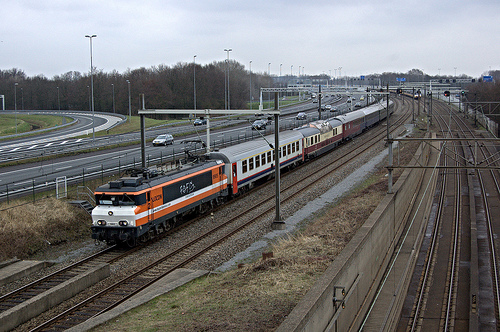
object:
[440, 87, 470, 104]
street lights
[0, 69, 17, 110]
trees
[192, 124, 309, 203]
carriage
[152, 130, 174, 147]
cars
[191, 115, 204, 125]
cars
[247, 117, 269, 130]
cars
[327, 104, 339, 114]
cars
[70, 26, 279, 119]
light poles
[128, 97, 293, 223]
rails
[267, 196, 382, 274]
soil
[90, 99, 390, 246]
train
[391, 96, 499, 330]
rail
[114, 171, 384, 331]
grass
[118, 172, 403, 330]
gravel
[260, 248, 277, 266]
tree stump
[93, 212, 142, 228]
headlights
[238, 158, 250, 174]
window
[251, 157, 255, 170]
window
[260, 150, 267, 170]
window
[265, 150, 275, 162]
window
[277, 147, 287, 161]
window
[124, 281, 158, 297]
rail line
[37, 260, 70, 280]
rail line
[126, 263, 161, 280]
rail line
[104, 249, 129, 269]
rail line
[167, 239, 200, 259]
rail line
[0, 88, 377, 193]
highway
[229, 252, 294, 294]
grass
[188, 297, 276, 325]
dirt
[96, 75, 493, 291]
train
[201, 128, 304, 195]
train car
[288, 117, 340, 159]
train car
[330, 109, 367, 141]
train car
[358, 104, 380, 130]
train car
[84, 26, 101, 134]
lighting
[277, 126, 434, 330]
barrier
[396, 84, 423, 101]
train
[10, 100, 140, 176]
highway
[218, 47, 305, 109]
street lights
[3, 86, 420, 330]
rail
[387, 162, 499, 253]
tracks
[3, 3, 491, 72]
grey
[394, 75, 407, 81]
billboard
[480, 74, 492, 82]
billboard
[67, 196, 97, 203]
stairs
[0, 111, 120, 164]
road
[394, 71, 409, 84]
signs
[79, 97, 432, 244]
transit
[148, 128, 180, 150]
car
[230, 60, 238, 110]
trees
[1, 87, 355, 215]
road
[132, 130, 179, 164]
car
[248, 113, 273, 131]
car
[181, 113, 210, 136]
car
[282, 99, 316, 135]
car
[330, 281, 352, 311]
signal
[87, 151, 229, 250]
engine